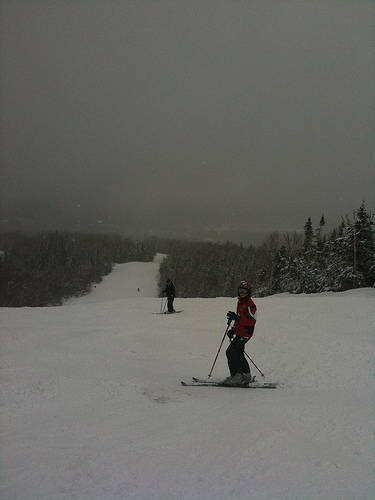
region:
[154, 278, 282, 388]
two people on a ski slope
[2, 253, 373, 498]
snow-covered ski slope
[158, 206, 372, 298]
trees on the right side of the slope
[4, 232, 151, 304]
trees on the left side of the slope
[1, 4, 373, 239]
dark cloudy sky above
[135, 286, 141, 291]
person skiing at the bottom of the hill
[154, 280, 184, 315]
skier in all black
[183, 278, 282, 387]
skier with the red coat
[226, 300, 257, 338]
the skier's red ski jacket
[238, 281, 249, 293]
red ski helmet and black goggles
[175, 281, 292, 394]
person on skis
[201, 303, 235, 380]
skinny black ski pole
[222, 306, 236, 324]
hand wrapped around the handle of the ski pole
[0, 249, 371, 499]
ground is covered in snow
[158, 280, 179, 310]
person wearing all black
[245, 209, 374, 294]
white snow on the pine trees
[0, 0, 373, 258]
the sky is gray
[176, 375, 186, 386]
top of the ski is bent upwards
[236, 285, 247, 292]
goggles on the face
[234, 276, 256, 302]
red helmet on the head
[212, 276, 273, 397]
skier wearing a red black and white jacket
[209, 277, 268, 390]
skier wearing a red black and white helmet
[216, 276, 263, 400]
skier posing for a picture on a mountain path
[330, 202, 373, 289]
snow-covered pine trees line the course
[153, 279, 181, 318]
skier wearing black coat and pants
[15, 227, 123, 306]
a large amount of pine trees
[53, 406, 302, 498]
snow marked by the tracks of skis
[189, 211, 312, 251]
mountains in the distance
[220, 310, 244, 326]
black ski glove used for warmth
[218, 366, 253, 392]
grey ski boots that snap onto skis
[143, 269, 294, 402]
two skiers on a slop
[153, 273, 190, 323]
a skier on a slop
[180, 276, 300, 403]
a skier holding two ski poles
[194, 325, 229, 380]
a black ski pole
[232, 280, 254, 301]
a skier wearing a ski helmet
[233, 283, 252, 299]
a skier wearing goggles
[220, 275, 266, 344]
a skier wearing a red and white ski helmet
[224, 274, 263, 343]
a skier wearing a red and white ski jacket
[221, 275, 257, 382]
a skier wearing black ski pants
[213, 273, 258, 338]
a skier wearing black gloves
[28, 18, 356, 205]
a gray overcast sky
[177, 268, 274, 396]
a person wearing a red jacket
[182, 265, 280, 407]
a skier holding a ski pole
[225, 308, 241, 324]
a black glove covering a hand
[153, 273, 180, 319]
a person dressed in a black jacket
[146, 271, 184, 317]
a person wearing black pants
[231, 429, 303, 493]
ski tracks in the snow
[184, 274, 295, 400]
a person wearing black snow pants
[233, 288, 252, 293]
snow goggles covering a face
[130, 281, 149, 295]
a person skiing in the distance